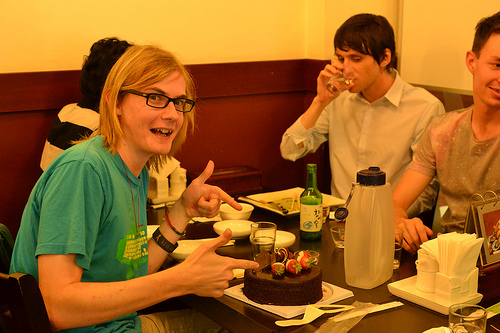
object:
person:
[279, 12, 445, 216]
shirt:
[9, 135, 154, 331]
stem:
[271, 263, 286, 277]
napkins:
[418, 228, 483, 277]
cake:
[242, 248, 324, 306]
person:
[39, 37, 134, 180]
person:
[393, 11, 499, 255]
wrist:
[395, 217, 405, 225]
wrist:
[313, 94, 333, 107]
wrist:
[164, 263, 187, 294]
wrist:
[162, 198, 189, 236]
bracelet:
[151, 227, 179, 253]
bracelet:
[162, 211, 186, 236]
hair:
[70, 46, 196, 175]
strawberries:
[285, 259, 302, 275]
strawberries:
[297, 250, 313, 269]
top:
[356, 166, 387, 186]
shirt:
[36, 101, 101, 183]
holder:
[386, 232, 484, 315]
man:
[8, 44, 260, 333]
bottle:
[342, 167, 396, 290]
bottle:
[298, 163, 322, 240]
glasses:
[120, 85, 197, 113]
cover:
[355, 166, 385, 186]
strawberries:
[272, 262, 286, 276]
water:
[325, 72, 354, 95]